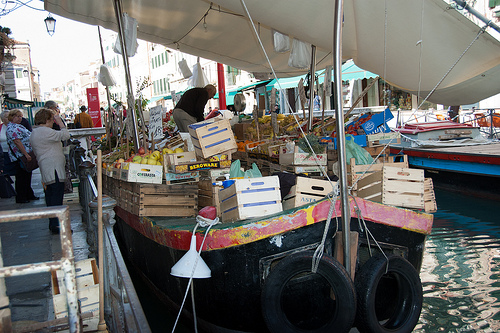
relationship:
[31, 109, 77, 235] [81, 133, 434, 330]
people looking at boat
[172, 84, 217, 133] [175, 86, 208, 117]
man wearing shirt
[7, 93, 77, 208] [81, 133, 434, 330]
people are watching boat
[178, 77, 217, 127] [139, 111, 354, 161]
man weighing produce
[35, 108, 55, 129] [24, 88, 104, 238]
head of woman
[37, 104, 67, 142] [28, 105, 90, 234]
arm of woman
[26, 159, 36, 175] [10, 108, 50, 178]
hand of woman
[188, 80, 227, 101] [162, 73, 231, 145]
head of man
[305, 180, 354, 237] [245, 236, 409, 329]
rope tied to tire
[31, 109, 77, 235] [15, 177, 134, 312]
people on dock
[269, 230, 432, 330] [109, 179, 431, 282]
tires hanging on boat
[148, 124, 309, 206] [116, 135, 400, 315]
boxes on boat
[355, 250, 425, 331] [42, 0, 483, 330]
tire hanging from boat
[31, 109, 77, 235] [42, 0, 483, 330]
people standing next to boat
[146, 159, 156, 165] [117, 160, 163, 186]
fruit lying inside box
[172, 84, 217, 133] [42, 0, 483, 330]
man standing on top of boat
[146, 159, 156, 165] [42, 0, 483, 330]
fruit lying inside boat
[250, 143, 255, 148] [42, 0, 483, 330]
fruit lying inside boat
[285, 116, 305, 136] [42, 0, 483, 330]
fruit lying inside boat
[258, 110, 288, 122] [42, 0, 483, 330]
fruit lying inside boat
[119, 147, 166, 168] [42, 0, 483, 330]
fruit lying inside boat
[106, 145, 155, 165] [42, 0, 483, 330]
fruit lying inside boat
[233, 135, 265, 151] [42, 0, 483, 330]
fruit lying inside boat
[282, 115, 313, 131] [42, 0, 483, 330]
fruit lying inside boat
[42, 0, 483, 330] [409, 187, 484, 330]
boat floating in water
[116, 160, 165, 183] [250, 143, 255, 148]
box filled with fruit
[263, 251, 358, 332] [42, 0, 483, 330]
tires hanging from boat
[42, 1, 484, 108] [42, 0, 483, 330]
canopy covering boat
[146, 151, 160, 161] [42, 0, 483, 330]
apple lying inside boat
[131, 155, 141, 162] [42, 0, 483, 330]
apple lying inside boat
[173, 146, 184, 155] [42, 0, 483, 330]
apple lying inside boat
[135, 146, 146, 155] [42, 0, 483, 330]
apple lying inside boat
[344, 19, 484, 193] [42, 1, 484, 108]
string securing canopy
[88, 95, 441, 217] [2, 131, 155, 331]
produce market attached to dock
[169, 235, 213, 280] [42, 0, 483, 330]
funnel attached to boat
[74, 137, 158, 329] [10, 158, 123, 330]
railing along dock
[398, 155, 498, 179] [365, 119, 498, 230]
stripes on boat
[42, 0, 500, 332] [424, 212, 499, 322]
boat docked in water